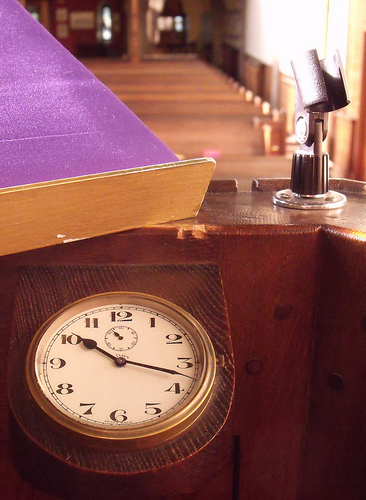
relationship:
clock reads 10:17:
[6, 256, 240, 479] [43, 314, 214, 429]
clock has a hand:
[6, 256, 240, 479] [73, 331, 114, 367]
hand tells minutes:
[125, 358, 188, 381] [33, 294, 204, 432]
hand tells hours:
[73, 331, 114, 367] [30, 303, 212, 431]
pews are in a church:
[72, 46, 295, 157] [1, 2, 364, 500]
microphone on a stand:
[287, 41, 356, 119] [274, 110, 354, 214]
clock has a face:
[6, 256, 240, 479] [30, 289, 212, 431]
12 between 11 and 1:
[106, 305, 137, 326] [82, 309, 160, 332]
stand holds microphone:
[274, 110, 354, 214] [287, 41, 356, 119]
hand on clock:
[73, 331, 114, 367] [6, 256, 240, 479]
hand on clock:
[125, 358, 188, 381] [6, 256, 240, 479]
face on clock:
[30, 289, 212, 431] [6, 256, 240, 479]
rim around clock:
[24, 289, 219, 444] [6, 256, 240, 479]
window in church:
[98, 6, 118, 47] [1, 2, 364, 500]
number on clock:
[140, 399, 166, 418] [6, 256, 240, 479]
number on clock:
[78, 399, 99, 418] [6, 256, 240, 479]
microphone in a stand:
[287, 41, 356, 119] [274, 110, 354, 214]